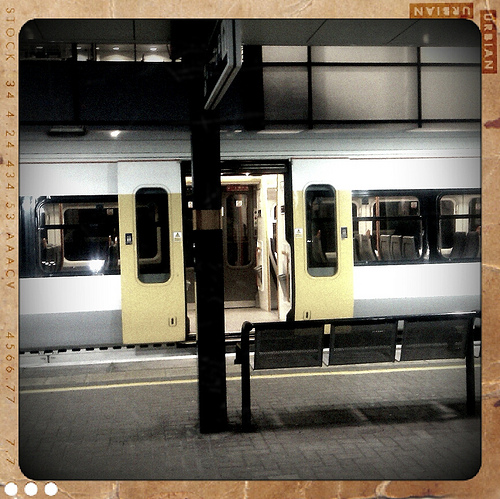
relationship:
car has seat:
[17, 120, 489, 361] [370, 228, 425, 262]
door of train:
[105, 155, 366, 352] [17, 120, 489, 361]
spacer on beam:
[23, 339, 199, 373] [21, 349, 196, 364]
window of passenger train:
[353, 181, 485, 266] [17, 120, 489, 361]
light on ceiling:
[98, 123, 132, 141] [31, 120, 474, 136]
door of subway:
[105, 155, 366, 352] [17, 120, 489, 361]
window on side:
[32, 189, 125, 280] [17, 120, 489, 361]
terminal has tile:
[34, 23, 486, 485] [34, 355, 478, 486]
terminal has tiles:
[34, 23, 486, 485] [34, 355, 478, 486]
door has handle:
[112, 156, 193, 355] [123, 232, 134, 247]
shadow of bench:
[223, 391, 484, 438] [232, 309, 484, 431]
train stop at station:
[17, 120, 489, 361] [34, 23, 486, 485]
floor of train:
[217, 269, 273, 331] [17, 120, 489, 361]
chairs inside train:
[370, 228, 425, 262] [17, 120, 489, 361]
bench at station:
[232, 309, 484, 431] [34, 23, 486, 485]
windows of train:
[353, 181, 485, 266] [17, 120, 489, 361]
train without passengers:
[17, 120, 489, 361] [41, 179, 482, 278]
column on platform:
[164, 46, 241, 443] [34, 355, 478, 486]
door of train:
[112, 156, 193, 355] [17, 120, 489, 361]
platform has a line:
[34, 355, 478, 486] [36, 358, 475, 388]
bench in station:
[232, 309, 484, 431] [28, 87, 480, 486]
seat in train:
[368, 231, 420, 264] [17, 120, 489, 361]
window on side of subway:
[353, 181, 485, 266] [24, 124, 467, 346]